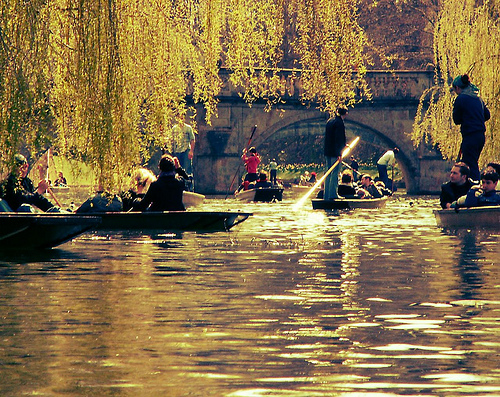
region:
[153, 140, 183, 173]
head of a person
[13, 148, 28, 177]
head of a person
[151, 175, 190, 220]
back of a person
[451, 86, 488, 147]
body of a person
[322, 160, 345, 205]
leg of a person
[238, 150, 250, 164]
arm of a person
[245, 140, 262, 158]
head of a person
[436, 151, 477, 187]
head of a person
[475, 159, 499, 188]
head of a person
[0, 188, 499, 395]
a river lit by the sun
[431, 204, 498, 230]
a boat with people in it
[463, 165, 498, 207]
a person on the boat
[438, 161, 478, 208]
a person on the boat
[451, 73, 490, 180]
a person paddling the boat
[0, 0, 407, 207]
a large tree hanging over the river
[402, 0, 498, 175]
a large tree hanging over the river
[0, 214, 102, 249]
a boat with people inside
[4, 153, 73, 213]
a man paddling the boat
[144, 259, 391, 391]
water is calm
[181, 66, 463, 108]
bridge over the water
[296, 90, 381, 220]
man standing on the back of the boat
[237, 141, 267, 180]
person in the boat with a red jacket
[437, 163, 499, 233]
people are sitting in a boat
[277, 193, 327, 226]
sun is shining on the water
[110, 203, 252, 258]
green boat in the water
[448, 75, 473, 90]
person is wearing a bandana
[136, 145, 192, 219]
person sitting inside a row boat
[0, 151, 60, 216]
person sitting inside a row boat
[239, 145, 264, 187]
person sitting inside a row boat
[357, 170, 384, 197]
person sitting inside a row boat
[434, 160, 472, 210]
person sitting inside a row boat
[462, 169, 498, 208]
person sitting inside a row boat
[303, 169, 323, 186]
person sitting inside a row boat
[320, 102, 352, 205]
person standing on top of a row boat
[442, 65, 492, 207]
person standing on top of a row boat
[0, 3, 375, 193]
leaves on hanging branches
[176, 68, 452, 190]
side of stone bridge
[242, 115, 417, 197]
archway under stone bridge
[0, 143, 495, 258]
people in row boats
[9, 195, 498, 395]
reflection on water surface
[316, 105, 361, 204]
person standing on boat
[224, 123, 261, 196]
person with boat oar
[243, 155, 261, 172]
red shirt on boater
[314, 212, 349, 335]
reflection of person on water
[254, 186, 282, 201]
stern of row boat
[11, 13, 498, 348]
many people in the background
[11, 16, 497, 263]
many people on boats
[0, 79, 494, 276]
five boats in the background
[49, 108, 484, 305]
reflection in the water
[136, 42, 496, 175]
bridge in the background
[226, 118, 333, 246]
person wearing pink top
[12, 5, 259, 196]
leaves in the background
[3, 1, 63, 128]
yellow plants hanging from overhead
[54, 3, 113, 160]
yellow plants hanging from overhead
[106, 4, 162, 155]
yellow plants hanging from overhead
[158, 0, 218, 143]
yellow plants hanging from overhead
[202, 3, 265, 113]
yellow plants hanging from overhead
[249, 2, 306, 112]
yellow plants hanging from overhead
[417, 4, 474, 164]
yellow plants hanging from overhead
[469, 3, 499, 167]
yellow plants hanging from overhead